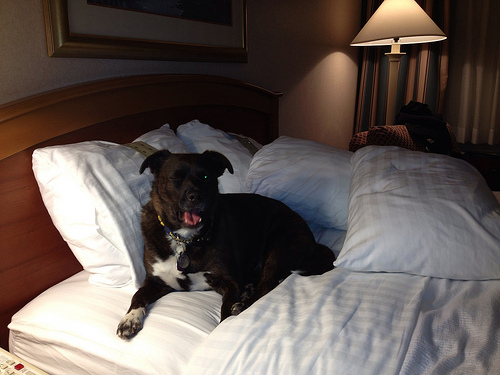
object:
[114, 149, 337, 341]
dog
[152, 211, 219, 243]
collar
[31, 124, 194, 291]
pillow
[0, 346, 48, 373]
phone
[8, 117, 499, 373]
bed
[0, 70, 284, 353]
headboard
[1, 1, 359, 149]
wall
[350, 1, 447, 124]
lamp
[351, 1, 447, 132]
curtain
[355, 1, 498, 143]
window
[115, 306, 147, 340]
paw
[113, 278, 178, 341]
leg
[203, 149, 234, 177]
ear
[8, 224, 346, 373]
sheets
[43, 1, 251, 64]
painting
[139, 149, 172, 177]
ears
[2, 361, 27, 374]
buttons